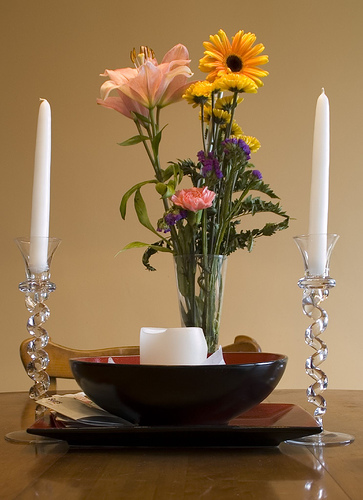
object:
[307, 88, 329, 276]
candle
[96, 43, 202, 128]
lily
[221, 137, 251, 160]
flower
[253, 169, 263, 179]
flower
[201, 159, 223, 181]
flower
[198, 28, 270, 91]
daisy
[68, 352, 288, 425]
bowl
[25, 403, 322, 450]
plate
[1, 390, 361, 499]
table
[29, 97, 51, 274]
candle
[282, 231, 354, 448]
candle holder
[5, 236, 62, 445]
candle holder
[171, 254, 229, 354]
vase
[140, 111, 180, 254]
stem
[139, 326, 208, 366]
candle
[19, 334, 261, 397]
chair